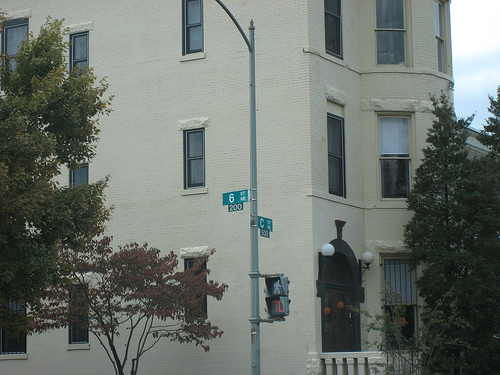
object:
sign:
[219, 184, 252, 211]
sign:
[255, 211, 274, 233]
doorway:
[312, 238, 372, 354]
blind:
[372, 110, 416, 160]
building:
[0, 0, 500, 373]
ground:
[420, 127, 442, 155]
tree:
[26, 238, 228, 373]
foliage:
[26, 245, 228, 352]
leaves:
[401, 90, 498, 369]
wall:
[133, 70, 196, 126]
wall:
[166, 86, 357, 280]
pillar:
[318, 357, 325, 374]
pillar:
[327, 352, 339, 373]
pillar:
[340, 353, 348, 373]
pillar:
[349, 352, 360, 374]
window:
[182, 124, 209, 190]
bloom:
[200, 344, 212, 354]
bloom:
[217, 281, 227, 293]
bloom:
[130, 241, 142, 249]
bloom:
[112, 329, 119, 336]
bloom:
[42, 322, 54, 330]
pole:
[247, 15, 262, 373]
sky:
[461, 27, 498, 88]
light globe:
[319, 242, 336, 257]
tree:
[10, 139, 86, 267]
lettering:
[224, 190, 255, 207]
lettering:
[257, 216, 272, 231]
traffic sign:
[259, 267, 299, 317]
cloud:
[454, 66, 484, 97]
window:
[377, 104, 418, 204]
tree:
[400, 99, 484, 373]